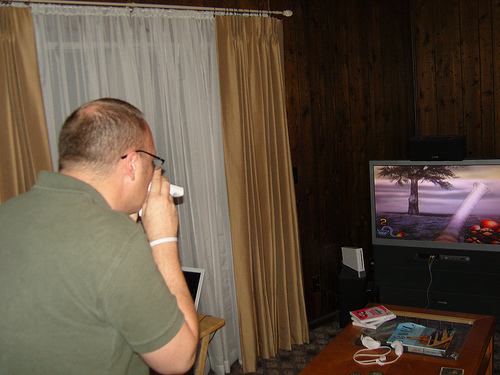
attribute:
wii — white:
[337, 244, 368, 282]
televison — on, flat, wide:
[369, 160, 497, 253]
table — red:
[299, 301, 496, 375]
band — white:
[146, 237, 183, 248]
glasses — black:
[118, 150, 175, 169]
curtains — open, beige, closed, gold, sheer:
[214, 16, 313, 375]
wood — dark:
[286, 6, 498, 132]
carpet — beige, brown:
[264, 320, 353, 375]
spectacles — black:
[153, 155, 165, 171]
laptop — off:
[181, 262, 208, 315]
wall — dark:
[298, 2, 498, 293]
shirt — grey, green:
[4, 169, 186, 373]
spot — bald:
[81, 104, 101, 119]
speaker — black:
[406, 136, 469, 160]